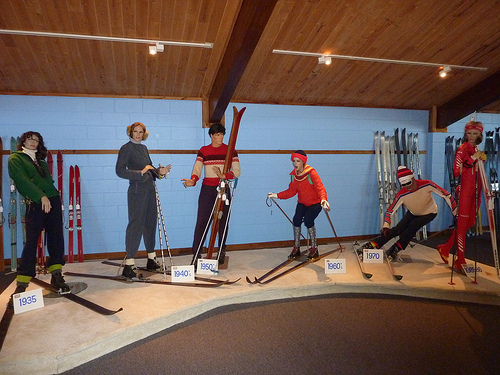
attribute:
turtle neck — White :
[17, 143, 46, 169]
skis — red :
[66, 164, 86, 266]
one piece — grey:
[116, 141, 166, 257]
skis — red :
[206, 105, 247, 259]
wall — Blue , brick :
[223, 103, 498, 243]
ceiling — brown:
[267, 19, 464, 110]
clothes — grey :
[128, 148, 152, 236]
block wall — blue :
[253, 115, 356, 212]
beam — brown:
[199, 2, 284, 128]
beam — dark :
[207, 0, 274, 124]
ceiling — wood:
[1, 0, 498, 130]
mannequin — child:
[258, 138, 380, 278]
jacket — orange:
[292, 172, 331, 217]